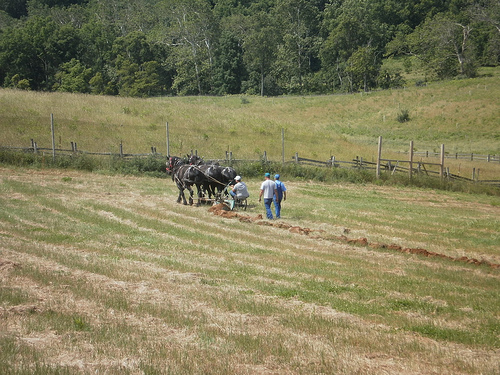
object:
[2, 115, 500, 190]
fence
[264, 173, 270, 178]
hat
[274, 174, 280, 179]
hat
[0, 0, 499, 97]
trees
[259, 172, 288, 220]
two men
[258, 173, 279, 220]
man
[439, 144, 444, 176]
fence post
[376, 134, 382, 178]
fence post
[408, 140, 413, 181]
fence post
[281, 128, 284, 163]
fence post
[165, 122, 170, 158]
fence post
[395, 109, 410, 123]
green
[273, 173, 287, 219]
man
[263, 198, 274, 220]
short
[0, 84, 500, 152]
shrub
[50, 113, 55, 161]
pole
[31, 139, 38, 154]
pole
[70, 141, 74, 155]
pole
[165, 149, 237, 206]
horses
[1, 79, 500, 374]
grass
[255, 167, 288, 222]
men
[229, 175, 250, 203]
man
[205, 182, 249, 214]
cart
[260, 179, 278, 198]
tee shirt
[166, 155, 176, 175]
head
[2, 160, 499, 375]
field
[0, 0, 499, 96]
brush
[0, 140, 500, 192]
property line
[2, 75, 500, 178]
hillside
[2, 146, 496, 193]
edge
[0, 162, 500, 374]
enclosure